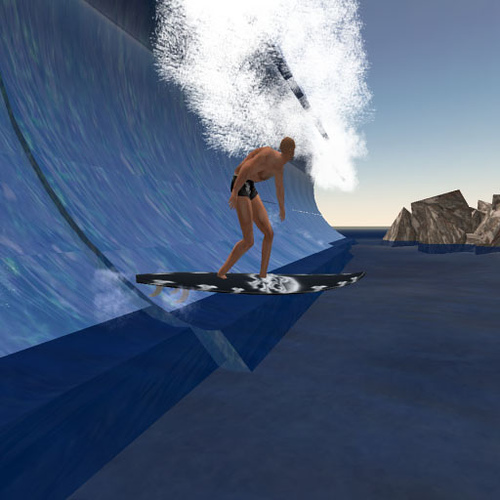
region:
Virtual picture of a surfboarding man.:
[0, 1, 495, 491]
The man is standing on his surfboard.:
[131, 135, 369, 297]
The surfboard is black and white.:
[132, 265, 367, 295]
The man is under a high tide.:
[150, 5, 407, 265]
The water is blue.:
[163, 301, 486, 496]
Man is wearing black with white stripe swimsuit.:
[228, 170, 259, 200]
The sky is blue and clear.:
[375, 5, 495, 180]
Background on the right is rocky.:
[393, 191, 498, 242]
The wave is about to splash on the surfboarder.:
[165, 1, 370, 148]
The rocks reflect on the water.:
[404, 242, 499, 257]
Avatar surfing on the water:
[122, 117, 382, 295]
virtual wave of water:
[22, 2, 409, 115]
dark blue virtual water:
[72, 336, 377, 452]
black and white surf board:
[123, 254, 368, 305]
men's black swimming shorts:
[222, 159, 282, 226]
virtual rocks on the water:
[376, 182, 496, 261]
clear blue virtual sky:
[384, 29, 474, 142]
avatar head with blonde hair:
[273, 134, 308, 171]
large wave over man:
[49, 2, 390, 328]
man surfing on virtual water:
[119, 110, 417, 318]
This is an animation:
[19, 28, 454, 469]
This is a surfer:
[15, 30, 447, 362]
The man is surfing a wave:
[145, 18, 354, 330]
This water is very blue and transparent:
[17, 313, 448, 453]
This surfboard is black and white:
[125, 251, 380, 303]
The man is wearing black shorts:
[225, 160, 262, 206]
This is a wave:
[37, 65, 218, 285]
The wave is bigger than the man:
[41, 41, 319, 296]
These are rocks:
[366, 187, 496, 244]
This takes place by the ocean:
[84, 91, 405, 483]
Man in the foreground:
[183, 128, 308, 296]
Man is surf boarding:
[208, 121, 300, 294]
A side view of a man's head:
[275, 126, 302, 168]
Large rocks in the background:
[383, 173, 499, 261]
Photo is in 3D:
[2, 2, 499, 496]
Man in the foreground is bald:
[273, 130, 301, 165]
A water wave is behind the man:
[2, 43, 345, 363]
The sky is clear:
[312, 2, 499, 223]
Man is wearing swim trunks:
[224, 170, 268, 217]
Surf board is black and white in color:
[129, 261, 369, 296]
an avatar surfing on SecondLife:
[5, 7, 494, 360]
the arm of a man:
[269, 172, 294, 224]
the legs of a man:
[209, 199, 276, 279]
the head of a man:
[278, 137, 299, 166]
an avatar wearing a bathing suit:
[221, 123, 320, 281]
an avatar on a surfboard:
[126, 120, 392, 295]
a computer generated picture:
[16, 10, 495, 378]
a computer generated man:
[210, 128, 319, 284]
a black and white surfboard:
[130, 262, 371, 301]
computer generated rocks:
[380, 174, 493, 277]